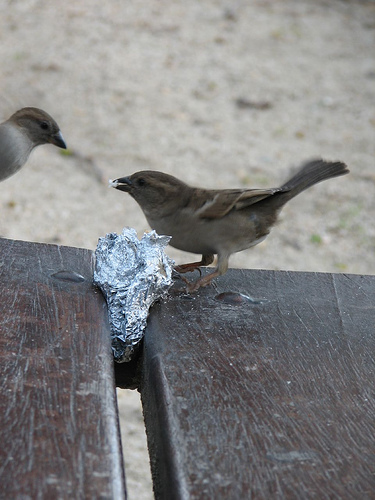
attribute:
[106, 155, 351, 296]
bird — brown, tan, eating, competing, small, bown, standing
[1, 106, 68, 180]
bird — bully, brown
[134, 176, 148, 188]
eye — black, round, small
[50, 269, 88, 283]
screw — metal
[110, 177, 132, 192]
beak — black, small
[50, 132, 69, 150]
beak — black, small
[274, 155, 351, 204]
tail — feathery, small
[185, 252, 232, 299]
leg — small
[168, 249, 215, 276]
leg — small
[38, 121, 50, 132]
eye — small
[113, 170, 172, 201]
head — small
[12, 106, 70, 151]
head — small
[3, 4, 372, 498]
ground — dirt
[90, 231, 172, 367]
foil — aluminum, trash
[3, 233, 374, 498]
table — brown, weathered, cracked, wooden